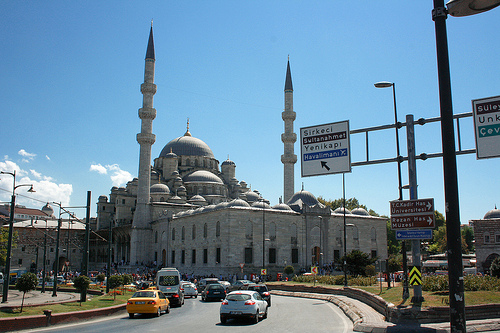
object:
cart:
[422, 7, 470, 332]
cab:
[126, 289, 170, 319]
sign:
[299, 119, 353, 176]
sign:
[470, 94, 499, 160]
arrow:
[318, 160, 335, 171]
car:
[201, 284, 227, 302]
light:
[373, 83, 408, 294]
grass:
[362, 279, 498, 314]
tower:
[134, 25, 160, 276]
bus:
[154, 268, 184, 307]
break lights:
[171, 294, 180, 298]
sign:
[391, 197, 436, 214]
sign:
[389, 211, 435, 228]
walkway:
[272, 285, 415, 331]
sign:
[408, 260, 424, 290]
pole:
[405, 111, 425, 315]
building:
[93, 22, 390, 277]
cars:
[180, 282, 199, 298]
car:
[246, 285, 271, 307]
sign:
[389, 226, 434, 239]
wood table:
[321, 7, 411, 72]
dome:
[157, 137, 213, 158]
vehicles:
[2, 268, 275, 325]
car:
[220, 290, 268, 322]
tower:
[277, 54, 301, 211]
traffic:
[55, 267, 269, 324]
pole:
[432, 2, 466, 331]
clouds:
[0, 162, 76, 212]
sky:
[2, 1, 494, 221]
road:
[8, 271, 354, 327]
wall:
[297, 122, 349, 178]